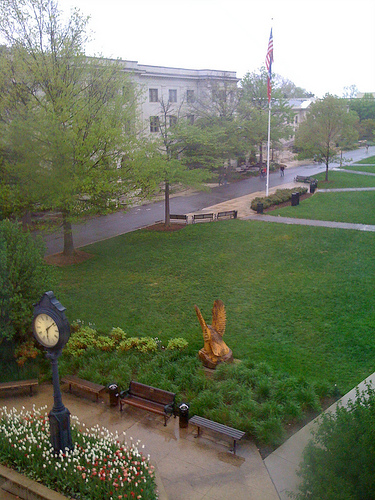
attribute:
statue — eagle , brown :
[188, 297, 235, 372]